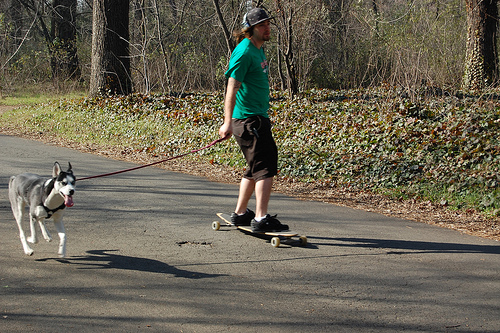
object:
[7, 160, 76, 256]
dog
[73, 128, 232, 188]
leash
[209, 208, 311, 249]
skateboard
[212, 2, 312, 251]
man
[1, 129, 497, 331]
street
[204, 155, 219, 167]
leaves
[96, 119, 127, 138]
grass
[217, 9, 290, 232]
man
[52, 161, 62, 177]
an ear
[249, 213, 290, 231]
shoe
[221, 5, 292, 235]
man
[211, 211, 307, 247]
black skateboard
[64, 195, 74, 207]
tongue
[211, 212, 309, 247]
black shoes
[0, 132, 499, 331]
road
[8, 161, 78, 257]
grey dog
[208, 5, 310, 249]
skateboarder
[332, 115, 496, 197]
leaves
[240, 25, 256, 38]
headphones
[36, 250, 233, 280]
shadow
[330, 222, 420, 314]
ground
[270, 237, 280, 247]
wheel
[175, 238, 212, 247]
pothole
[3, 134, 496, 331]
asphalt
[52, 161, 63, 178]
ear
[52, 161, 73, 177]
ears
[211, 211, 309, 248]
board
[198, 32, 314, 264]
man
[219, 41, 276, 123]
shirt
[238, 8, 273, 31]
cap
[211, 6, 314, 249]
man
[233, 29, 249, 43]
hair